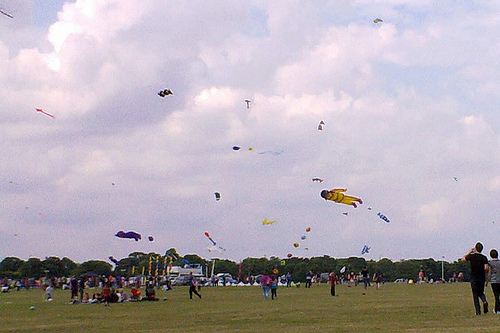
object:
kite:
[34, 106, 57, 120]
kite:
[156, 87, 173, 100]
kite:
[361, 243, 370, 256]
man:
[326, 270, 338, 297]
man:
[187, 271, 202, 301]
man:
[67, 273, 80, 304]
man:
[75, 273, 90, 304]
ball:
[28, 303, 36, 311]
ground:
[0, 281, 499, 333]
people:
[259, 269, 273, 300]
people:
[43, 284, 53, 303]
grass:
[0, 277, 500, 331]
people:
[131, 284, 144, 302]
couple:
[459, 240, 499, 316]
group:
[62, 264, 161, 303]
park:
[2, 247, 500, 332]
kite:
[318, 187, 364, 209]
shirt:
[464, 253, 490, 286]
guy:
[460, 241, 491, 315]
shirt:
[257, 276, 274, 286]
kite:
[262, 216, 280, 226]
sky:
[0, 0, 499, 262]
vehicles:
[172, 272, 206, 286]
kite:
[202, 232, 218, 246]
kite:
[113, 228, 141, 242]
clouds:
[0, 0, 499, 263]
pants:
[187, 289, 202, 299]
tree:
[0, 255, 25, 286]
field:
[0, 284, 499, 333]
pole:
[440, 260, 445, 282]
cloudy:
[0, 0, 499, 261]